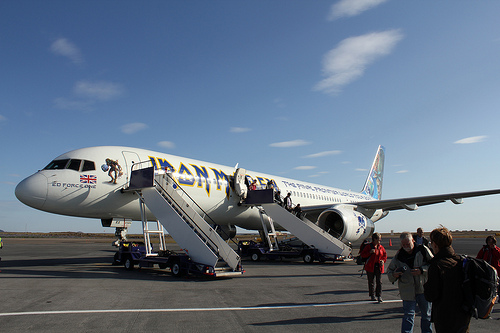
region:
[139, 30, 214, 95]
Sky is blue color.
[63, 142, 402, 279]
One plane is seen.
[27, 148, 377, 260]
Plane is white color.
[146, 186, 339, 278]
Two steps are attached to the plane.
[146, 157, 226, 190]
Letters are blue and yellow.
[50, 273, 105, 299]
Road is grey color.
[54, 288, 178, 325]
White lines on road.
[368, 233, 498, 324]
People are standing in road.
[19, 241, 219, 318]
Shadow falls on road.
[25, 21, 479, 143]
Sky is clear with few clouds.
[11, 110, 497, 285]
The plane is white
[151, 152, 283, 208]
The plane says Iron Maiden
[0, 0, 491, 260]
The sky is blue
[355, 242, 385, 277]
The jacket is red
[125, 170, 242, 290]
The steps are white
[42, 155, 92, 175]
The cockpit has windows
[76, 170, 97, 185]
Union Jack flag beneath the windows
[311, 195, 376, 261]
The engine is big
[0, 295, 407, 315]
The white stripe is on the tarmac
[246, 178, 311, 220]
people are on the stairs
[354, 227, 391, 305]
a woman in red jacket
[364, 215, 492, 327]
a group of people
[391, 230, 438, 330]
a man in blue jeans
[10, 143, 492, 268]
a very big aeroplane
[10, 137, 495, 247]
a very beautiful plane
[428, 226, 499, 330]
a man carrying a back pack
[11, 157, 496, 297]
an aeroplane in the runway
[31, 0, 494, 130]
very clear skies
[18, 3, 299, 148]
very clear blue skies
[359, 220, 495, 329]
a croud of people at the airport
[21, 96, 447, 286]
plane is large and white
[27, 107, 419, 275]
plane is large and white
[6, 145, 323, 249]
white plane on runway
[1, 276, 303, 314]
runway beneath the plane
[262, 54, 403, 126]
white cloud in the sky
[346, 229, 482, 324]
People outside the plane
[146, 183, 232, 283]
stairs leading down from plane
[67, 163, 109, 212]
British logo on plane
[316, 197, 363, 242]
engine of plane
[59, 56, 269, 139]
Blue sky above the plane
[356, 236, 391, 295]
woman with red jacket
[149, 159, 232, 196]
The word "Iron"